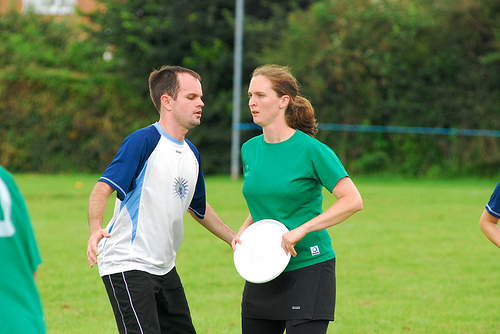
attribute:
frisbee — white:
[228, 216, 293, 287]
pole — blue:
[232, 3, 244, 181]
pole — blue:
[322, 118, 498, 145]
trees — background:
[2, 0, 498, 179]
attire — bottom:
[104, 124, 206, 332]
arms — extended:
[77, 127, 154, 266]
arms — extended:
[178, 139, 233, 249]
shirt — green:
[232, 135, 374, 257]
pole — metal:
[231, 9, 242, 181]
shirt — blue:
[113, 108, 207, 265]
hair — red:
[245, 62, 322, 137]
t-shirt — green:
[220, 60, 378, 278]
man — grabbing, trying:
[86, 65, 236, 327]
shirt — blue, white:
[93, 120, 205, 279]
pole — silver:
[233, 0, 245, 183]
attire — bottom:
[243, 257, 342, 320]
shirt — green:
[239, 128, 349, 272]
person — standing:
[73, 41, 227, 326]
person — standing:
[217, 70, 374, 331]